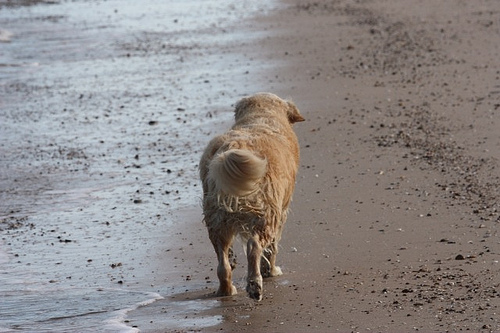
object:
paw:
[246, 280, 262, 302]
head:
[231, 92, 305, 125]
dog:
[197, 92, 305, 302]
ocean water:
[0, 5, 226, 331]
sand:
[289, 16, 497, 330]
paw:
[216, 286, 237, 296]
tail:
[210, 149, 270, 198]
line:
[191, 0, 268, 333]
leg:
[203, 219, 236, 291]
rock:
[455, 254, 464, 260]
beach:
[16, 15, 487, 326]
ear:
[231, 97, 249, 113]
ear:
[287, 100, 306, 124]